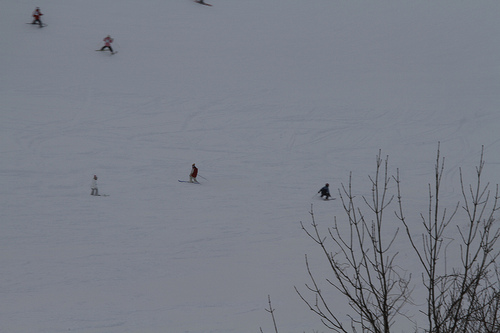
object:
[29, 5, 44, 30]
person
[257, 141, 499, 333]
tree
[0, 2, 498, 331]
snow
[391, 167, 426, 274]
branch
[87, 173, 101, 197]
skater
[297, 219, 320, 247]
twig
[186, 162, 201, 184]
man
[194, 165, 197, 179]
back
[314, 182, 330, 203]
skier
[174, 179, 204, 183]
ski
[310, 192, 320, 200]
pole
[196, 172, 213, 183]
pole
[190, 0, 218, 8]
man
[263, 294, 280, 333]
branch